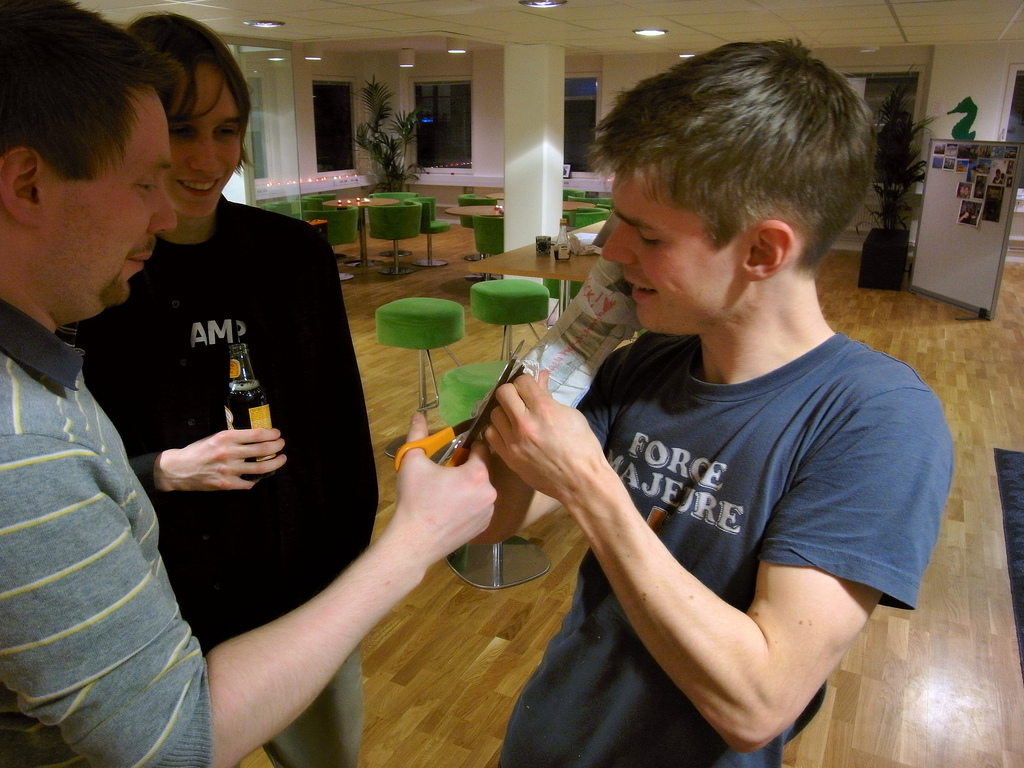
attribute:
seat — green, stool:
[383, 285, 470, 350]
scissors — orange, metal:
[322, 380, 563, 467]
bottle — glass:
[206, 342, 301, 442]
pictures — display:
[897, 121, 1021, 254]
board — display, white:
[897, 121, 1021, 254]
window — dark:
[392, 75, 498, 158]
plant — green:
[334, 82, 430, 178]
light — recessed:
[253, 0, 286, 33]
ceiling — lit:
[243, 9, 769, 93]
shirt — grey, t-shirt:
[579, 342, 960, 704]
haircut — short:
[618, 75, 907, 275]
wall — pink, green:
[382, 345, 504, 441]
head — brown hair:
[635, 86, 833, 260]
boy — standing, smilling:
[571, 86, 834, 660]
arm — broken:
[563, 445, 836, 722]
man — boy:
[563, 51, 1012, 722]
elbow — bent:
[702, 638, 849, 718]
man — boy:
[568, 70, 850, 718]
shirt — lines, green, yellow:
[8, 322, 217, 702]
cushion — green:
[375, 297, 464, 354]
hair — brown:
[603, 31, 878, 245]